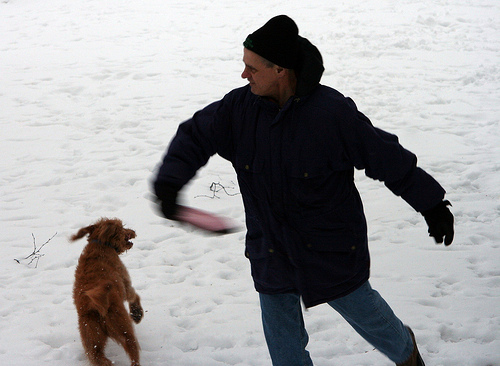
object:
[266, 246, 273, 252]
button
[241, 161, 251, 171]
button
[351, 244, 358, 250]
button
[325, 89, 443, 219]
arm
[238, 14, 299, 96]
head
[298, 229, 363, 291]
pocket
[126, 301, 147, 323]
dog's paw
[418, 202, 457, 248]
hand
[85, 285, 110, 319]
tail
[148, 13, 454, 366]
man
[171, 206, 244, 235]
frisbee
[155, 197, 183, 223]
hand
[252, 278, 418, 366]
jeans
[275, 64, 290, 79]
ear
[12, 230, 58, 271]
stick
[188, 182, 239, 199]
stick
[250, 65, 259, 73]
eye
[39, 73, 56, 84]
footprints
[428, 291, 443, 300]
footprints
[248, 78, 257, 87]
mouth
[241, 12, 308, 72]
hat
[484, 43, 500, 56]
footprints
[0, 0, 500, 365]
snow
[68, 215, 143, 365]
dog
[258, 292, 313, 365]
leg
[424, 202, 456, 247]
glove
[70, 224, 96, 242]
ear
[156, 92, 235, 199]
arm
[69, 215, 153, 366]
running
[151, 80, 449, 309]
coat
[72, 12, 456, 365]
they